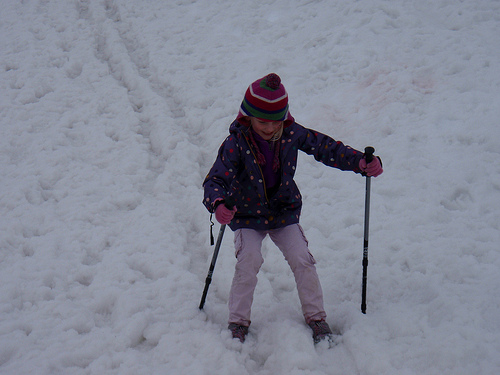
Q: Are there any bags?
A: No, there are no bags.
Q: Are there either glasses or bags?
A: No, there are no bags or glasses.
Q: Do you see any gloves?
A: Yes, there are gloves.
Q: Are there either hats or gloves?
A: Yes, there are gloves.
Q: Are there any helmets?
A: No, there are no helmets.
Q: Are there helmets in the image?
A: No, there are no helmets.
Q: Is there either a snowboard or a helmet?
A: No, there are no helmets or snowboards.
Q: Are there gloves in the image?
A: Yes, there are gloves.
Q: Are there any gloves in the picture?
A: Yes, there are gloves.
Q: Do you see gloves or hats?
A: Yes, there are gloves.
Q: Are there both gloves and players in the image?
A: No, there are gloves but no players.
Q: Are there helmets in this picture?
A: No, there are no helmets.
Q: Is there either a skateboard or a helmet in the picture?
A: No, there are no helmets or skateboards.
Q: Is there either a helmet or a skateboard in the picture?
A: No, there are no helmets or skateboards.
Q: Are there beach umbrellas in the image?
A: No, there are no beach umbrellas.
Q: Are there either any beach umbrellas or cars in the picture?
A: No, there are no beach umbrellas or cars.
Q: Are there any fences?
A: No, there are no fences.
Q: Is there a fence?
A: No, there are no fences.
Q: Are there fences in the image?
A: No, there are no fences.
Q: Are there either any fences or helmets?
A: No, there are no fences or helmets.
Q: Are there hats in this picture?
A: Yes, there is a hat.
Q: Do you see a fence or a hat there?
A: Yes, there is a hat.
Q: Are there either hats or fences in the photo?
A: Yes, there is a hat.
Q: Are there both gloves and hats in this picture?
A: Yes, there are both a hat and gloves.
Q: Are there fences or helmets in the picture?
A: No, there are no fences or helmets.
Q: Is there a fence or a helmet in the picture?
A: No, there are no fences or helmets.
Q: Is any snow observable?
A: Yes, there is snow.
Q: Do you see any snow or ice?
A: Yes, there is snow.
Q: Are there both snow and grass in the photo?
A: No, there is snow but no grass.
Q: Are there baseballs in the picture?
A: No, there are no baseballs.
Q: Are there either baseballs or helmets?
A: No, there are no baseballs or helmets.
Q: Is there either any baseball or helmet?
A: No, there are no baseballs or helmets.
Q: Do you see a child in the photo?
A: Yes, there is a child.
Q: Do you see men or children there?
A: Yes, there is a child.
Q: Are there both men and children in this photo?
A: No, there is a child but no men.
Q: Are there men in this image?
A: No, there are no men.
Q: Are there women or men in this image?
A: No, there are no men or women.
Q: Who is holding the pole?
A: The child is holding the pole.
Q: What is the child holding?
A: The child is holding the pole.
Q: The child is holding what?
A: The child is holding the pole.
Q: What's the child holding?
A: The child is holding the pole.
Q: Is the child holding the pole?
A: Yes, the child is holding the pole.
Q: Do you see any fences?
A: No, there are no fences.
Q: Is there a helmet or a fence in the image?
A: No, there are no fences or helmets.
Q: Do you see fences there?
A: No, there are no fences.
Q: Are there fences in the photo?
A: No, there are no fences.